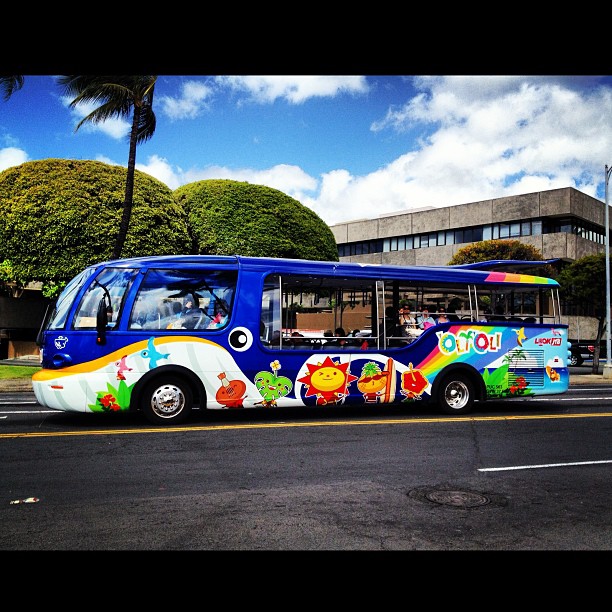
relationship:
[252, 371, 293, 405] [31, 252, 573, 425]
heart on bus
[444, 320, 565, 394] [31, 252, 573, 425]
scene on bus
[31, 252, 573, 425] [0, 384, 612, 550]
bus on road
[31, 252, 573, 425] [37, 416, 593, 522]
bus on street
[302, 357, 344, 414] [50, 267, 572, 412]
decal on bus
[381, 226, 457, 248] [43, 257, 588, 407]
window on bus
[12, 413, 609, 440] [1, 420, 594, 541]
yellowline on street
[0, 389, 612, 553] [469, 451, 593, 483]
road has line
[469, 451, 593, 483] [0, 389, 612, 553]
line on road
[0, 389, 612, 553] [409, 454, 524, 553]
road has patch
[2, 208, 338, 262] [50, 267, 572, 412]
tree next to bus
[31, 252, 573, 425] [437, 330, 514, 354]
bus has words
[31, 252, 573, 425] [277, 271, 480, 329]
bus has windows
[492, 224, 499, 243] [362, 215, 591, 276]
window on building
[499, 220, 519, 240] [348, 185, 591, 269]
window on building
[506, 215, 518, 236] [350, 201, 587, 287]
window on building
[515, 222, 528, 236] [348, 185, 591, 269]
window on building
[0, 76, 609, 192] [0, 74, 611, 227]
clouds are in clouds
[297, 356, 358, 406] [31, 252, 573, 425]
decal on bus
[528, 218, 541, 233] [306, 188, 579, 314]
window on building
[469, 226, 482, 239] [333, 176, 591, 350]
window on building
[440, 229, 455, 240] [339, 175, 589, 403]
window on building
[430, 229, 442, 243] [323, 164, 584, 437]
window on building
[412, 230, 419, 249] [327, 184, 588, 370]
window on building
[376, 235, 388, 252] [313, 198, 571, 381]
window on building